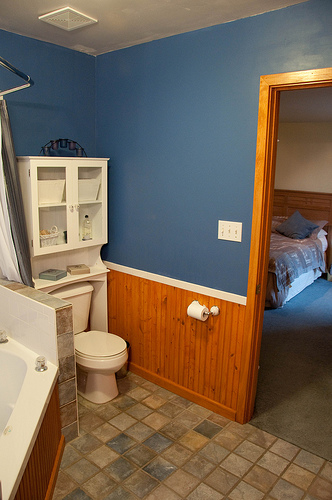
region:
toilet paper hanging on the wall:
[182, 299, 219, 321]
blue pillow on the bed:
[275, 207, 320, 241]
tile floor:
[80, 421, 244, 495]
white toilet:
[51, 282, 129, 401]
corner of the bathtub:
[0, 331, 54, 496]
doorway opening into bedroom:
[235, 63, 330, 422]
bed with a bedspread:
[265, 182, 330, 313]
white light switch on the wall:
[215, 217, 243, 244]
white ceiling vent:
[36, 6, 98, 32]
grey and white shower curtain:
[0, 92, 35, 287]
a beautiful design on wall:
[45, 4, 110, 46]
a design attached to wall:
[46, 9, 105, 37]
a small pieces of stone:
[82, 417, 301, 497]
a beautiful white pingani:
[61, 299, 143, 400]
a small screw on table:
[25, 350, 69, 381]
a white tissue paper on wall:
[176, 296, 230, 338]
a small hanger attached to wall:
[203, 310, 214, 317]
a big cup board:
[19, 151, 146, 253]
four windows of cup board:
[48, 174, 98, 245]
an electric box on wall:
[207, 208, 259, 248]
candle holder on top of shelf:
[34, 129, 107, 157]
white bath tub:
[0, 345, 43, 498]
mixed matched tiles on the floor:
[102, 415, 202, 499]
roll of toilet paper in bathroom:
[175, 281, 229, 344]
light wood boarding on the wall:
[149, 317, 235, 381]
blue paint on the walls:
[159, 199, 205, 257]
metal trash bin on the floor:
[121, 334, 134, 388]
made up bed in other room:
[281, 199, 318, 306]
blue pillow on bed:
[277, 207, 324, 256]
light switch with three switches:
[205, 213, 255, 266]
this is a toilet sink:
[79, 335, 127, 404]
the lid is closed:
[86, 336, 116, 358]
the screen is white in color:
[91, 334, 118, 373]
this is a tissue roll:
[186, 300, 214, 320]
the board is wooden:
[179, 331, 245, 395]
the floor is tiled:
[114, 425, 202, 493]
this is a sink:
[3, 361, 21, 396]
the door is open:
[252, 232, 331, 384]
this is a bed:
[273, 230, 311, 294]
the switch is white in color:
[213, 218, 242, 242]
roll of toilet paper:
[167, 276, 239, 345]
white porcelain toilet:
[43, 279, 157, 446]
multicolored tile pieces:
[58, 366, 291, 493]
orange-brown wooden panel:
[112, 261, 286, 423]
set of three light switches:
[206, 209, 251, 259]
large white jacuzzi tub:
[3, 298, 93, 491]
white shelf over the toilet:
[15, 147, 122, 352]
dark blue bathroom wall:
[92, 49, 284, 293]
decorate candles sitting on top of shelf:
[34, 126, 95, 169]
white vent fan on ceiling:
[30, 0, 112, 41]